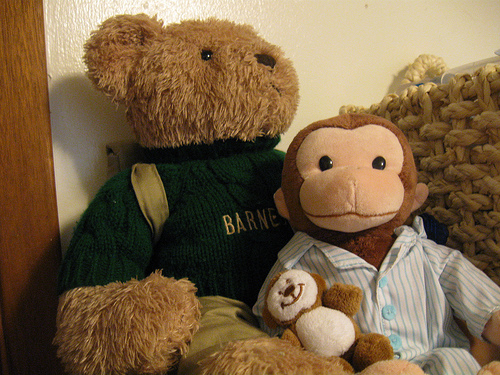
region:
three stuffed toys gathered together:
[48, 7, 498, 367]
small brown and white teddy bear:
[261, 265, 392, 374]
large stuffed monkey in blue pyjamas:
[251, 115, 499, 373]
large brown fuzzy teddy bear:
[53, 3, 348, 373]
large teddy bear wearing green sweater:
[51, 6, 370, 373]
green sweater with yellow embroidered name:
[55, 117, 328, 289]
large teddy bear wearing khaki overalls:
[53, 10, 386, 367]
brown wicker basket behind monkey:
[325, 53, 497, 285]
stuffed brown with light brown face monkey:
[246, 117, 497, 373]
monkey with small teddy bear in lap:
[251, 99, 498, 369]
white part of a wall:
[287, 9, 381, 64]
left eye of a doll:
[374, 155, 391, 173]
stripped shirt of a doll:
[404, 286, 450, 348]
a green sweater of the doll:
[183, 212, 247, 272]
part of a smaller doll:
[299, 297, 369, 362]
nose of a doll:
[260, 56, 277, 73]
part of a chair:
[451, 131, 480, 226]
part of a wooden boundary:
[1, 158, 60, 283]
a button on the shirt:
[380, 302, 397, 330]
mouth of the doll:
[294, 201, 373, 216]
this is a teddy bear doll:
[62, 20, 274, 372]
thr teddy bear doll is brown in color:
[56, 30, 271, 366]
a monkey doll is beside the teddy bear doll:
[281, 116, 456, 367]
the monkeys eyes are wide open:
[310, 153, 392, 174]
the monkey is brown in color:
[288, 125, 399, 257]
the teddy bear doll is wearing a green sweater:
[157, 166, 261, 258]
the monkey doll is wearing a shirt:
[383, 264, 435, 316]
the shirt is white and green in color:
[381, 260, 436, 331]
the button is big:
[378, 303, 405, 318]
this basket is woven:
[433, 87, 494, 199]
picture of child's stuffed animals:
[12, 3, 499, 368]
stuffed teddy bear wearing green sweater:
[65, 17, 343, 374]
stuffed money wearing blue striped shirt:
[264, 113, 499, 373]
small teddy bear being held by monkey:
[261, 269, 396, 368]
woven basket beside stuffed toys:
[380, 57, 499, 274]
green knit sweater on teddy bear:
[65, 140, 304, 300]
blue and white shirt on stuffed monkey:
[262, 227, 499, 374]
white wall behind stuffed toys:
[53, 1, 486, 246]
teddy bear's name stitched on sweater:
[218, 203, 294, 233]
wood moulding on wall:
[4, 2, 65, 374]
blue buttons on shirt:
[369, 279, 411, 356]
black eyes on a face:
[306, 146, 425, 179]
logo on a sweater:
[219, 206, 282, 240]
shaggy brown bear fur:
[157, 59, 202, 115]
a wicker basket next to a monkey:
[439, 89, 498, 200]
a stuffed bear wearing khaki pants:
[86, 14, 284, 374]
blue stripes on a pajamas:
[411, 271, 444, 331]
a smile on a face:
[274, 299, 305, 307]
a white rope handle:
[404, 51, 448, 91]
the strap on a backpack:
[128, 159, 169, 229]